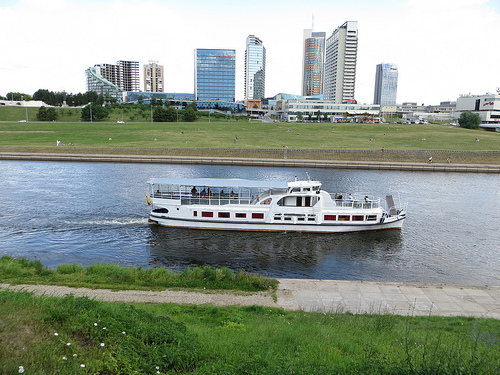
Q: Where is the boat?
A: A river.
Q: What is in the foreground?
A: Green grass.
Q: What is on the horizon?
A: Tall buildings.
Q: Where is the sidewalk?
A: Alongside the river.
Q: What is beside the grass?
A: Sidewalk.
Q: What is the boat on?
A: Water.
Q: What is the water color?
A: Blue.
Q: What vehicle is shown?
A: Boat.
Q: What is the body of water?
A: River.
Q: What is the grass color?
A: Green.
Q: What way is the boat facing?
A: Right.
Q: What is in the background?
A: City.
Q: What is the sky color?
A: White.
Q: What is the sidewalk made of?
A: Concrete.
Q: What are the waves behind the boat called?
A: Wake.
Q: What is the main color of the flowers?
A: White.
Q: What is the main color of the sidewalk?
A: Gray.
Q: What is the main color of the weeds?
A: Green.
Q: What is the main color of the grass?
A: Green.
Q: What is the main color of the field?
A: Green.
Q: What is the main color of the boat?
A: White.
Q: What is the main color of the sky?
A: White.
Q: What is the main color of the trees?
A: Green.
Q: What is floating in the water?
A: A boat.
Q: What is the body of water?
A: A canal.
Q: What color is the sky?
A: White.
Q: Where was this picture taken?
A: From a grassy hill.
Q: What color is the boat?
A: White with a blue stripe.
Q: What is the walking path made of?
A: Concrete.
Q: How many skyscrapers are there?
A: Seven.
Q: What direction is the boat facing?
A: Right.